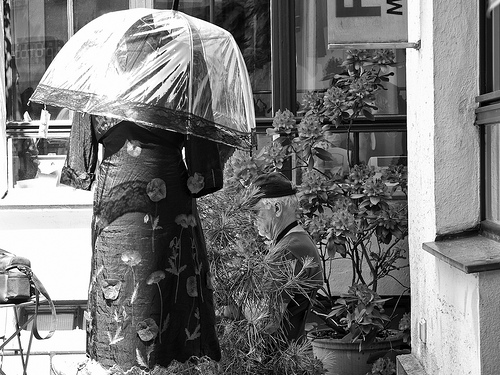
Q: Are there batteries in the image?
A: No, there are no batteries.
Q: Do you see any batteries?
A: No, there are no batteries.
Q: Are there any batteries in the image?
A: No, there are no batteries.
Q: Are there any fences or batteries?
A: No, there are no batteries or fences.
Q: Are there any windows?
A: Yes, there is a window.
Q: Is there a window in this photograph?
A: Yes, there is a window.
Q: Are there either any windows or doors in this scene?
A: Yes, there is a window.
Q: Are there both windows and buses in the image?
A: No, there is a window but no buses.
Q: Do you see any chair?
A: No, there are no chairs.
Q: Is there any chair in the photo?
A: No, there are no chairs.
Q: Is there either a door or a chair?
A: No, there are no chairs or doors.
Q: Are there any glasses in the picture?
A: No, there are no glasses.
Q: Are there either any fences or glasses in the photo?
A: No, there are no glasses or fences.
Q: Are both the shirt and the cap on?
A: Yes, both the shirt and the cap are on.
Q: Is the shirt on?
A: Yes, the shirt is on.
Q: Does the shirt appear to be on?
A: Yes, the shirt is on.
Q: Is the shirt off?
A: No, the shirt is on.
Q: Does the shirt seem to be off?
A: No, the shirt is on.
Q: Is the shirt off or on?
A: The shirt is on.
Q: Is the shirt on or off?
A: The shirt is on.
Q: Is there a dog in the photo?
A: No, there are no dogs.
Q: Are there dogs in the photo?
A: No, there are no dogs.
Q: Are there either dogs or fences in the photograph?
A: No, there are no dogs or fences.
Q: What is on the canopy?
A: The tag is on the canopy.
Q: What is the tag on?
A: The tag is on the canopy.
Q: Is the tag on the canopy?
A: Yes, the tag is on the canopy.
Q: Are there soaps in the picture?
A: No, there are no soaps.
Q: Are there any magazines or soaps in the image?
A: No, there are no soaps or magazines.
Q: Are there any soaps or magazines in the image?
A: No, there are no soaps or magazines.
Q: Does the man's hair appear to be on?
A: Yes, the hair is on.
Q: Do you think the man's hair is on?
A: Yes, the hair is on.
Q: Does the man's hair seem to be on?
A: Yes, the hair is on.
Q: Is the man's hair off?
A: No, the hair is on.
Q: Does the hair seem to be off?
A: No, the hair is on.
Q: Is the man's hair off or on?
A: The hair is on.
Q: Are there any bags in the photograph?
A: Yes, there is a bag.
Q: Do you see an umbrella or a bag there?
A: Yes, there is a bag.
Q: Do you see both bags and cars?
A: No, there is a bag but no cars.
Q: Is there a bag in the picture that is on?
A: Yes, there is a bag that is on.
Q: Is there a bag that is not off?
A: Yes, there is a bag that is on.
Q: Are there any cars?
A: No, there are no cars.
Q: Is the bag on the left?
A: Yes, the bag is on the left of the image.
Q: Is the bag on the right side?
A: No, the bag is on the left of the image.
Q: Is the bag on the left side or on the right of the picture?
A: The bag is on the left of the image.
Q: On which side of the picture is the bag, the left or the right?
A: The bag is on the left of the image.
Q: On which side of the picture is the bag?
A: The bag is on the left of the image.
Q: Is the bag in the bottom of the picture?
A: Yes, the bag is in the bottom of the image.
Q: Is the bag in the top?
A: No, the bag is in the bottom of the image.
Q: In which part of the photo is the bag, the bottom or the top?
A: The bag is in the bottom of the image.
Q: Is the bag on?
A: Yes, the bag is on.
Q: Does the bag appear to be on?
A: Yes, the bag is on.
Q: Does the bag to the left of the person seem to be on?
A: Yes, the bag is on.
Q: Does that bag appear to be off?
A: No, the bag is on.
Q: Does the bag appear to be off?
A: No, the bag is on.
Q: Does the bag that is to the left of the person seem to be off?
A: No, the bag is on.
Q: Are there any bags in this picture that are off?
A: No, there is a bag but it is on.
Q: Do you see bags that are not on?
A: No, there is a bag but it is on.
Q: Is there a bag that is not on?
A: No, there is a bag but it is on.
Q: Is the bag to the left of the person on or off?
A: The bag is on.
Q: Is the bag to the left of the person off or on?
A: The bag is on.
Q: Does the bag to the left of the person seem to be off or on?
A: The bag is on.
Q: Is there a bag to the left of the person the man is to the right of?
A: Yes, there is a bag to the left of the person.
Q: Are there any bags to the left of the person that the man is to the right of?
A: Yes, there is a bag to the left of the person.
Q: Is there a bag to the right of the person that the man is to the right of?
A: No, the bag is to the left of the person.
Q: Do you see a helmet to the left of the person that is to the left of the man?
A: No, there is a bag to the left of the person.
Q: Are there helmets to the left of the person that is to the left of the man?
A: No, there is a bag to the left of the person.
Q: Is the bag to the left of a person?
A: Yes, the bag is to the left of a person.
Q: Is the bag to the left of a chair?
A: No, the bag is to the left of a person.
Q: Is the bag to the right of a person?
A: No, the bag is to the left of a person.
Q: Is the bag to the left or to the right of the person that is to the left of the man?
A: The bag is to the left of the person.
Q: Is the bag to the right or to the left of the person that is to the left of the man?
A: The bag is to the left of the person.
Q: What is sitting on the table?
A: The bag is sitting on the table.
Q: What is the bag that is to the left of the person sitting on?
A: The bag is sitting on the table.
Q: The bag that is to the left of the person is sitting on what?
A: The bag is sitting on the table.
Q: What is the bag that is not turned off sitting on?
A: The bag is sitting on the table.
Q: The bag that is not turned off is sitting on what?
A: The bag is sitting on the table.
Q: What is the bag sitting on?
A: The bag is sitting on the table.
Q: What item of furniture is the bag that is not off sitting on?
A: The bag is sitting on the table.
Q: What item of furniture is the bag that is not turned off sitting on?
A: The bag is sitting on the table.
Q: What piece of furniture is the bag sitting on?
A: The bag is sitting on the table.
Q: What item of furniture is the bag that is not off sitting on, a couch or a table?
A: The bag is sitting on a table.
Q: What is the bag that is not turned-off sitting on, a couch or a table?
A: The bag is sitting on a table.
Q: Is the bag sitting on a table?
A: Yes, the bag is sitting on a table.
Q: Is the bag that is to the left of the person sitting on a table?
A: Yes, the bag is sitting on a table.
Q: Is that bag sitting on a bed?
A: No, the bag is sitting on a table.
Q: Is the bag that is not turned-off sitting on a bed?
A: No, the bag is sitting on a table.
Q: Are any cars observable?
A: No, there are no cars.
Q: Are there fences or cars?
A: No, there are no cars or fences.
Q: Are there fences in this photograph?
A: No, there are no fences.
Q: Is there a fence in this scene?
A: No, there are no fences.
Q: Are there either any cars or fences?
A: No, there are no fences or cars.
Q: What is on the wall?
A: The sign is on the wall.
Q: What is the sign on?
A: The sign is on the wall.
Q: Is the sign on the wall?
A: Yes, the sign is on the wall.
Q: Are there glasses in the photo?
A: No, there are no glasses.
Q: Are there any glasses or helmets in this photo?
A: No, there are no glasses or helmets.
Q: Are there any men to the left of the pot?
A: Yes, there is a man to the left of the pot.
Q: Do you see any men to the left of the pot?
A: Yes, there is a man to the left of the pot.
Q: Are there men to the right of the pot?
A: No, the man is to the left of the pot.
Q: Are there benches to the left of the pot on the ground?
A: No, there is a man to the left of the pot.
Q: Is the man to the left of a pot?
A: Yes, the man is to the left of a pot.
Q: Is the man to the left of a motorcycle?
A: No, the man is to the left of a pot.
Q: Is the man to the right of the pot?
A: No, the man is to the left of the pot.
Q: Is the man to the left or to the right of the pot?
A: The man is to the left of the pot.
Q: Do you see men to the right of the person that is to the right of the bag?
A: Yes, there is a man to the right of the person.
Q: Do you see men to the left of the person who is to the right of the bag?
A: No, the man is to the right of the person.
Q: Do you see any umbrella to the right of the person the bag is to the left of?
A: No, there is a man to the right of the person.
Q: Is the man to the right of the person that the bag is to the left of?
A: Yes, the man is to the right of the person.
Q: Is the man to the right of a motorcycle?
A: No, the man is to the right of the person.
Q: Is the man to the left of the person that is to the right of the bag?
A: No, the man is to the right of the person.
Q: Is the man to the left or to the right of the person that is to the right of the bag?
A: The man is to the right of the person.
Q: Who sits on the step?
A: The man sits on the step.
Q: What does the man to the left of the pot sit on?
A: The man sits on the step.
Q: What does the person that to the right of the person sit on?
A: The man sits on the step.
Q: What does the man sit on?
A: The man sits on the step.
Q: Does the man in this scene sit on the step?
A: Yes, the man sits on the step.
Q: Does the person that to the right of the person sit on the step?
A: Yes, the man sits on the step.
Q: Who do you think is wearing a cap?
A: The man is wearing a cap.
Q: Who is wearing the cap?
A: The man is wearing a cap.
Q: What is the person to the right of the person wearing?
A: The man is wearing a cap.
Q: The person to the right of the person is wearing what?
A: The man is wearing a cap.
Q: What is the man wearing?
A: The man is wearing a cap.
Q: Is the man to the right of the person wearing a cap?
A: Yes, the man is wearing a cap.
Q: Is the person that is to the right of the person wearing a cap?
A: Yes, the man is wearing a cap.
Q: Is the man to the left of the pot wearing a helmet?
A: No, the man is wearing a cap.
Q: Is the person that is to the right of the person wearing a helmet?
A: No, the man is wearing a cap.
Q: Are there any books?
A: No, there are no books.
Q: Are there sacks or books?
A: No, there are no books or sacks.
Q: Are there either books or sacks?
A: No, there are no books or sacks.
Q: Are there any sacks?
A: No, there are no sacks.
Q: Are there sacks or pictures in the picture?
A: No, there are no sacks or pictures.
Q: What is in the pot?
A: The flower is in the pot.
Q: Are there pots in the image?
A: Yes, there is a pot.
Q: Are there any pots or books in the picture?
A: Yes, there is a pot.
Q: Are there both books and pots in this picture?
A: No, there is a pot but no books.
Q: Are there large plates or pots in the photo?
A: Yes, there is a large pot.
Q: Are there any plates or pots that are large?
A: Yes, the pot is large.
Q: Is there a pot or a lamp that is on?
A: Yes, the pot is on.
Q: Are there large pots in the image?
A: Yes, there is a large pot.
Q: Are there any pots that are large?
A: Yes, there is a pot that is large.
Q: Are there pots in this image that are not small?
A: Yes, there is a large pot.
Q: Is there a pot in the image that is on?
A: Yes, there is a pot that is on.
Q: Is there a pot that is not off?
A: Yes, there is a pot that is on.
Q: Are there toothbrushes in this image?
A: No, there are no toothbrushes.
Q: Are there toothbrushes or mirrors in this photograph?
A: No, there are no toothbrushes or mirrors.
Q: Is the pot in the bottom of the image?
A: Yes, the pot is in the bottom of the image.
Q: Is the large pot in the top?
A: No, the pot is in the bottom of the image.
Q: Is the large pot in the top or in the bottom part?
A: The pot is in the bottom of the image.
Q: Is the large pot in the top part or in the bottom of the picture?
A: The pot is in the bottom of the image.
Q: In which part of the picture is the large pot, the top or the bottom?
A: The pot is in the bottom of the image.